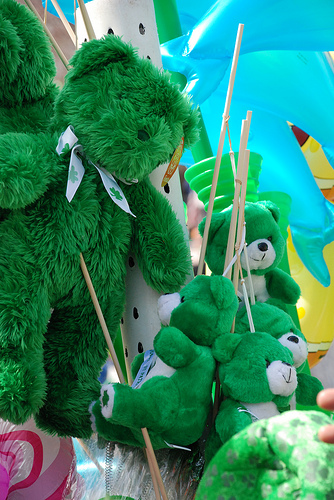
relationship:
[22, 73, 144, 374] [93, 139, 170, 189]
bear has mouth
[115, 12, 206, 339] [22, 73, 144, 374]
object near bear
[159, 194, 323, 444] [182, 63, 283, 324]
bears by sticks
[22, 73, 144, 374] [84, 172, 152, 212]
bear with tag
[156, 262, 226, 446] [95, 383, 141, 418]
bear has clover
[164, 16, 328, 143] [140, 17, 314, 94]
toys in background